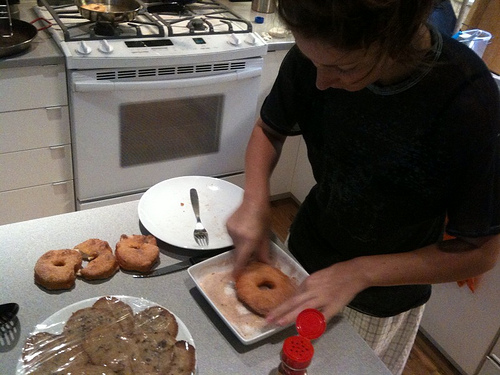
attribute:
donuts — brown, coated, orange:
[35, 233, 159, 292]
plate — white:
[17, 295, 200, 375]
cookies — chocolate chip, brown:
[22, 297, 195, 375]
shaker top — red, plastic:
[280, 309, 326, 370]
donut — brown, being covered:
[236, 262, 293, 315]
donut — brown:
[35, 248, 81, 290]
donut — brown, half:
[76, 238, 115, 280]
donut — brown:
[116, 233, 160, 274]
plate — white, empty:
[137, 176, 245, 249]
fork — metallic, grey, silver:
[188, 188, 207, 240]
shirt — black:
[259, 23, 498, 316]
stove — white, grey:
[34, 0, 267, 212]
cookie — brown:
[128, 334, 174, 374]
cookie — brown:
[86, 324, 130, 369]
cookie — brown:
[23, 332, 60, 367]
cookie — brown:
[66, 307, 120, 349]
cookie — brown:
[94, 295, 132, 327]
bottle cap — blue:
[254, 15, 263, 23]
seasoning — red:
[277, 308, 326, 374]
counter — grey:
[1, 200, 393, 374]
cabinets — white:
[0, 65, 76, 226]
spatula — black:
[0, 302, 19, 328]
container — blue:
[451, 29, 492, 58]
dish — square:
[187, 239, 312, 345]